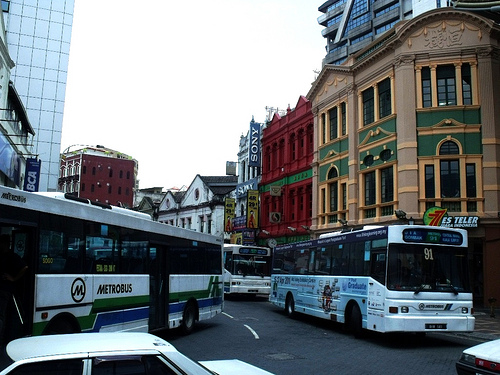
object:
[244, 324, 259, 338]
line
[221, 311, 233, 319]
line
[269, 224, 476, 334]
bus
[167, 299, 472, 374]
street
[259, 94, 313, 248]
building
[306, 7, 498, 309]
building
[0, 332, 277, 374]
car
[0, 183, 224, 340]
bus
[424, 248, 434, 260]
number 91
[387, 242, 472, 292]
windshield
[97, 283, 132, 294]
metrobus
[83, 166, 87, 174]
window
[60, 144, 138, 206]
building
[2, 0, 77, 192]
building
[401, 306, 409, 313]
headlight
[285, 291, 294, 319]
wheel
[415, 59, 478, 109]
window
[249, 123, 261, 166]
sign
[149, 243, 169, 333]
door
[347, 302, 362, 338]
wheel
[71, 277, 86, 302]
logo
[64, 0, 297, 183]
sky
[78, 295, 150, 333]
stripes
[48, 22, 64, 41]
window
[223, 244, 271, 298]
bus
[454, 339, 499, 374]
car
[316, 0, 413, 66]
building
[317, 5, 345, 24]
balcony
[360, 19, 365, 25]
windows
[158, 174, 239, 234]
building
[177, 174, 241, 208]
roof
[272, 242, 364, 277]
windows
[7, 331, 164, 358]
roof